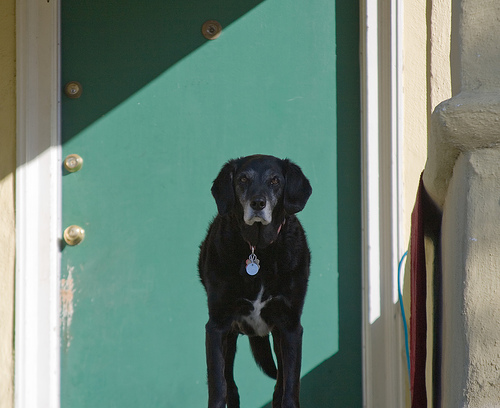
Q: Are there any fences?
A: No, there are no fences.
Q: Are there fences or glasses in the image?
A: No, there are no fences or glasses.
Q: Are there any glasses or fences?
A: No, there are no fences or glasses.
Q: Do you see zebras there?
A: No, there are no zebras.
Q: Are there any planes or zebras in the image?
A: No, there are no zebras or planes.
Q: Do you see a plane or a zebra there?
A: No, there are no zebras or airplanes.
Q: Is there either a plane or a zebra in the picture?
A: No, there are no zebras or airplanes.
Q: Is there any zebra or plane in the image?
A: No, there are no zebras or airplanes.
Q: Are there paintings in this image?
A: No, there are no paintings.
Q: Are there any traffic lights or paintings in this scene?
A: No, there are no paintings or traffic lights.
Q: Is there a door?
A: Yes, there is a door.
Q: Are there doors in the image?
A: Yes, there is a door.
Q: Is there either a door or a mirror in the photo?
A: Yes, there is a door.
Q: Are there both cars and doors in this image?
A: No, there is a door but no cars.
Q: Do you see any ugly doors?
A: Yes, there is an ugly door.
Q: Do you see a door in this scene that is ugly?
A: Yes, there is a door that is ugly.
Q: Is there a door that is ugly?
A: Yes, there is a door that is ugly.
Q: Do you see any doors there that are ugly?
A: Yes, there is a door that is ugly.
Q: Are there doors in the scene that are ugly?
A: Yes, there is a door that is ugly.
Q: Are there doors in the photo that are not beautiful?
A: Yes, there is a ugly door.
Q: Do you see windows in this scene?
A: No, there are no windows.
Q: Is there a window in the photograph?
A: No, there are no windows.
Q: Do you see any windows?
A: No, there are no windows.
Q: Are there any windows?
A: No, there are no windows.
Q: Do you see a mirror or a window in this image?
A: No, there are no windows or mirrors.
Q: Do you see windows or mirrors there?
A: No, there are no windows or mirrors.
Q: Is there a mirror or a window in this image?
A: No, there are no windows or mirrors.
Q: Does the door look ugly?
A: Yes, the door is ugly.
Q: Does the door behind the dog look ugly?
A: Yes, the door is ugly.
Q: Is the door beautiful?
A: No, the door is ugly.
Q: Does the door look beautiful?
A: No, the door is ugly.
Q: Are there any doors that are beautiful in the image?
A: No, there is a door but it is ugly.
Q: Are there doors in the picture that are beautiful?
A: No, there is a door but it is ugly.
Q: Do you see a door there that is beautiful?
A: No, there is a door but it is ugly.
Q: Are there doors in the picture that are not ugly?
A: No, there is a door but it is ugly.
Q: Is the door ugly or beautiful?
A: The door is ugly.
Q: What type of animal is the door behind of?
A: The door is behind the dog.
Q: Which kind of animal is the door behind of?
A: The door is behind the dog.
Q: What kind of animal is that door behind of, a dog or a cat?
A: The door is behind a dog.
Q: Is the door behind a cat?
A: No, the door is behind the dog.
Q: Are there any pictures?
A: No, there are no pictures.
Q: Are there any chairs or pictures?
A: No, there are no pictures or chairs.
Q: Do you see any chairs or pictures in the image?
A: No, there are no pictures or chairs.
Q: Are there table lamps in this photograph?
A: No, there are no table lamps.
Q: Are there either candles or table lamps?
A: No, there are no table lamps or candles.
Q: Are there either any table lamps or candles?
A: No, there are no table lamps or candles.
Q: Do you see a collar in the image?
A: Yes, there is a collar.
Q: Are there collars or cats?
A: Yes, there is a collar.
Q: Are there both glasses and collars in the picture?
A: No, there is a collar but no glasses.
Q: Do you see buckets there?
A: No, there are no buckets.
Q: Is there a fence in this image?
A: No, there are no fences.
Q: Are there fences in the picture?
A: No, there are no fences.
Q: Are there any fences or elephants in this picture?
A: No, there are no fences or elephants.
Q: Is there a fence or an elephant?
A: No, there are no fences or elephants.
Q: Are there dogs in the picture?
A: Yes, there is a dog.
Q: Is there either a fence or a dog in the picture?
A: Yes, there is a dog.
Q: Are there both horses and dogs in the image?
A: No, there is a dog but no horses.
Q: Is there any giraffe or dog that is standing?
A: Yes, the dog is standing.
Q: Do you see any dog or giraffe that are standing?
A: Yes, the dog is standing.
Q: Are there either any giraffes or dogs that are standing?
A: Yes, the dog is standing.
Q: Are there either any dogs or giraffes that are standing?
A: Yes, the dog is standing.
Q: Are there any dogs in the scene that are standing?
A: Yes, there is a dog that is standing.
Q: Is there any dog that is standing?
A: Yes, there is a dog that is standing.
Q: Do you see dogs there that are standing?
A: Yes, there is a dog that is standing.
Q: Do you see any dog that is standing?
A: Yes, there is a dog that is standing.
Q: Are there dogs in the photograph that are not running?
A: Yes, there is a dog that is standing.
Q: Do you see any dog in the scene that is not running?
A: Yes, there is a dog that is standing .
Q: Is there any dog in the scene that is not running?
A: Yes, there is a dog that is standing.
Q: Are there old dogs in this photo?
A: Yes, there is an old dog.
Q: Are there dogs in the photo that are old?
A: Yes, there is a dog that is old.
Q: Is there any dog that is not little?
A: Yes, there is a old dog.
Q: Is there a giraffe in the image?
A: No, there are no giraffes.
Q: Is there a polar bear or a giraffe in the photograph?
A: No, there are no giraffes or polar bears.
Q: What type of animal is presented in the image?
A: The animal is a dog.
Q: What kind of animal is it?
A: The animal is a dog.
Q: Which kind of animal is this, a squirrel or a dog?
A: That is a dog.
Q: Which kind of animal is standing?
A: The animal is a dog.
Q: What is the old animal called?
A: The animal is a dog.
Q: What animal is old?
A: The animal is a dog.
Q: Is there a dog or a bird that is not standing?
A: No, there is a dog but it is standing.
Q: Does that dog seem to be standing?
A: Yes, the dog is standing.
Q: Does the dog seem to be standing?
A: Yes, the dog is standing.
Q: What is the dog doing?
A: The dog is standing.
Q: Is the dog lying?
A: No, the dog is standing.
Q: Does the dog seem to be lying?
A: No, the dog is standing.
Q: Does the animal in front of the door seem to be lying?
A: No, the dog is standing.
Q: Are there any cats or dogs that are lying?
A: No, there is a dog but it is standing.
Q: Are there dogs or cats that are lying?
A: No, there is a dog but it is standing.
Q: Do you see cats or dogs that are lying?
A: No, there is a dog but it is standing.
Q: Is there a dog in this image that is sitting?
A: No, there is a dog but it is standing.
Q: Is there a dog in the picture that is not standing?
A: No, there is a dog but it is standing.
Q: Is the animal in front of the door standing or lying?
A: The dog is standing.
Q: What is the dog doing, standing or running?
A: The dog is standing.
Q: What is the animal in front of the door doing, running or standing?
A: The dog is standing.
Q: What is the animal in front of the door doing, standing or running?
A: The dog is standing.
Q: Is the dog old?
A: Yes, the dog is old.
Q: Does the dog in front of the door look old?
A: Yes, the dog is old.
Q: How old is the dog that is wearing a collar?
A: The dog is old.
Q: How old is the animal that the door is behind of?
A: The dog is old.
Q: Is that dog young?
A: No, the dog is old.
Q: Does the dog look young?
A: No, the dog is old.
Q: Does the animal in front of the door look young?
A: No, the dog is old.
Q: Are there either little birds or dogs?
A: No, there is a dog but it is old.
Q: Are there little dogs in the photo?
A: No, there is a dog but it is old.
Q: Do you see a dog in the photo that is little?
A: No, there is a dog but it is old.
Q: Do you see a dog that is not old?
A: No, there is a dog but it is old.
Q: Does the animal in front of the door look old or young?
A: The dog is old.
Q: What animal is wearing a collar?
A: The dog is wearing a collar.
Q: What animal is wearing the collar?
A: The dog is wearing a collar.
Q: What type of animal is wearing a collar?
A: The animal is a dog.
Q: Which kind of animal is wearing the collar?
A: The animal is a dog.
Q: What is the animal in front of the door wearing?
A: The dog is wearing a collar.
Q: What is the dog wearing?
A: The dog is wearing a collar.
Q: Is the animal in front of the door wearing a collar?
A: Yes, the dog is wearing a collar.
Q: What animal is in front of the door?
A: The dog is in front of the door.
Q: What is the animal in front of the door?
A: The animal is a dog.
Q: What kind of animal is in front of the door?
A: The animal is a dog.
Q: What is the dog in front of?
A: The dog is in front of the door.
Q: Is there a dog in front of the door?
A: Yes, there is a dog in front of the door.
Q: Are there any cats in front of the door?
A: No, there is a dog in front of the door.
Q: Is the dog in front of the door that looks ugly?
A: Yes, the dog is in front of the door.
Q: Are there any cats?
A: No, there are no cats.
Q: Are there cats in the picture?
A: No, there are no cats.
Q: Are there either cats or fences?
A: No, there are no cats or fences.